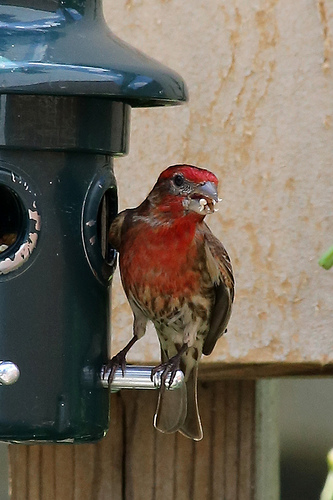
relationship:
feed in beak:
[199, 193, 223, 211] [189, 180, 219, 216]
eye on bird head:
[167, 174, 186, 189] [157, 163, 219, 217]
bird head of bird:
[157, 163, 219, 217] [102, 164, 235, 441]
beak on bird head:
[181, 180, 220, 219] [157, 163, 219, 217]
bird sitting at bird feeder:
[97, 160, 239, 444] [0, 0, 189, 445]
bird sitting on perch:
[102, 164, 235, 441] [101, 363, 185, 392]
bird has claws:
[102, 164, 235, 441] [148, 343, 187, 395]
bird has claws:
[102, 164, 235, 441] [100, 337, 135, 388]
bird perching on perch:
[102, 164, 235, 441] [101, 363, 185, 391]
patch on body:
[121, 216, 197, 303] [117, 212, 202, 348]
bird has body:
[97, 160, 239, 444] [117, 212, 202, 348]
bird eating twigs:
[97, 160, 239, 444] [196, 197, 221, 208]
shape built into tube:
[1, 160, 46, 281] [1, 148, 119, 444]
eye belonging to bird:
[172, 174, 183, 188] [97, 160, 239, 444]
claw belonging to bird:
[150, 354, 186, 390] [97, 160, 239, 444]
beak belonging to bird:
[189, 180, 219, 216] [97, 160, 239, 444]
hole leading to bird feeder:
[96, 187, 118, 264] [1, 1, 189, 446]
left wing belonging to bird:
[201, 230, 235, 355] [97, 160, 239, 444]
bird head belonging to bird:
[157, 163, 219, 217] [97, 160, 239, 444]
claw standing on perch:
[102, 349, 128, 385] [99, 362, 184, 394]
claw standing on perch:
[150, 354, 186, 390] [99, 362, 184, 394]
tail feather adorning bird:
[150, 345, 188, 434] [97, 160, 239, 444]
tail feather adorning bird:
[177, 359, 204, 441] [97, 160, 239, 444]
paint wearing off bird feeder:
[2, 167, 45, 279] [0, 0, 189, 445]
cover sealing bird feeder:
[1, 0, 190, 108] [1, 1, 189, 446]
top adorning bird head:
[157, 162, 219, 186] [148, 163, 218, 219]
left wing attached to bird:
[201, 230, 235, 355] [97, 160, 239, 444]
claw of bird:
[102, 349, 128, 385] [102, 164, 235, 441]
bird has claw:
[102, 164, 235, 441] [102, 349, 131, 381]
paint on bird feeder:
[0, 167, 42, 284] [1, 13, 175, 444]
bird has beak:
[102, 164, 235, 441] [189, 178, 219, 216]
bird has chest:
[102, 164, 235, 441] [124, 214, 204, 300]